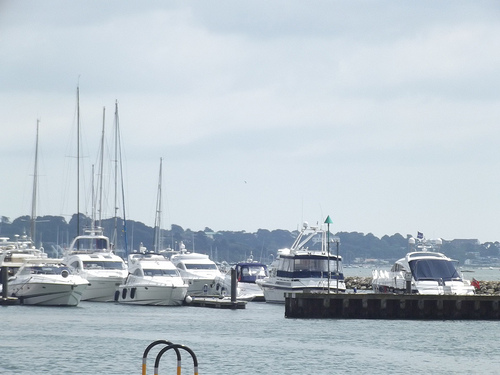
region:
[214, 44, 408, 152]
a clear blue sky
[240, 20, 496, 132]
clouds in the clear sky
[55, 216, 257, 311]
boats by the dock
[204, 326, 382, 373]
clear water in the lake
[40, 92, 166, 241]
posts in the background of photo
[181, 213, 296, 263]
green trees in the background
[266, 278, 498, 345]
a dock in the lake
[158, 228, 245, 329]
a boat in the lake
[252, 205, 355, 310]
a big boat in the middle of the lake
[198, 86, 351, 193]
a clear blue sky with clouds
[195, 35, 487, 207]
A cloudy blue sky.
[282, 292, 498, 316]
A grey wooden dock.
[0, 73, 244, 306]
A cluster of white boats.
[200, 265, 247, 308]
A small wooden dock.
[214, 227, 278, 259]
A cluster of tall trees.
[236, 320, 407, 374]
The baby blue water.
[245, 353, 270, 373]
The ripples in the water.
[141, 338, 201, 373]
Two arched blue and yellow railings with a gray band.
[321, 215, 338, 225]
A green triangular object.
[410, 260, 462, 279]
The large front window of the boat.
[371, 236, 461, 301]
This is a boat.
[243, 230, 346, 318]
This is a yacht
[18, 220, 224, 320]
This is a group of boats.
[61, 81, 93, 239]
This is a mast.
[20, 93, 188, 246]
These are boat masts.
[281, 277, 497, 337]
This is a pier.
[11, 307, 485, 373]
This is the water.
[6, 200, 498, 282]
These are trees.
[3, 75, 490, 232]
This is the sky.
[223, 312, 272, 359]
This is the color blue.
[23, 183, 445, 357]
Boats are on the water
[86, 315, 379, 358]
The water is blue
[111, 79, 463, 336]
The sky is hazy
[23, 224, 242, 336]
The boats are white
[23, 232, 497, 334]
There are 7 boats seen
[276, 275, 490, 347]
This is the boats dock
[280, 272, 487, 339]
The dock is black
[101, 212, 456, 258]
The rocks are black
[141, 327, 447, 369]
There are ripples in the water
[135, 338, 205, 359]
gray portion of hand rails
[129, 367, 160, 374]
yellow portion of hand rail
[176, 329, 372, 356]
white line in water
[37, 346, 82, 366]
small waves in blue water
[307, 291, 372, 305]
asphalt railing on dock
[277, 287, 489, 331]
large gray dock over the water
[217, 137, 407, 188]
clear blue skies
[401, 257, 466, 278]
blue clear window in boat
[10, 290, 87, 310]
blue stripe on front of boat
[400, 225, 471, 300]
large white modern boat